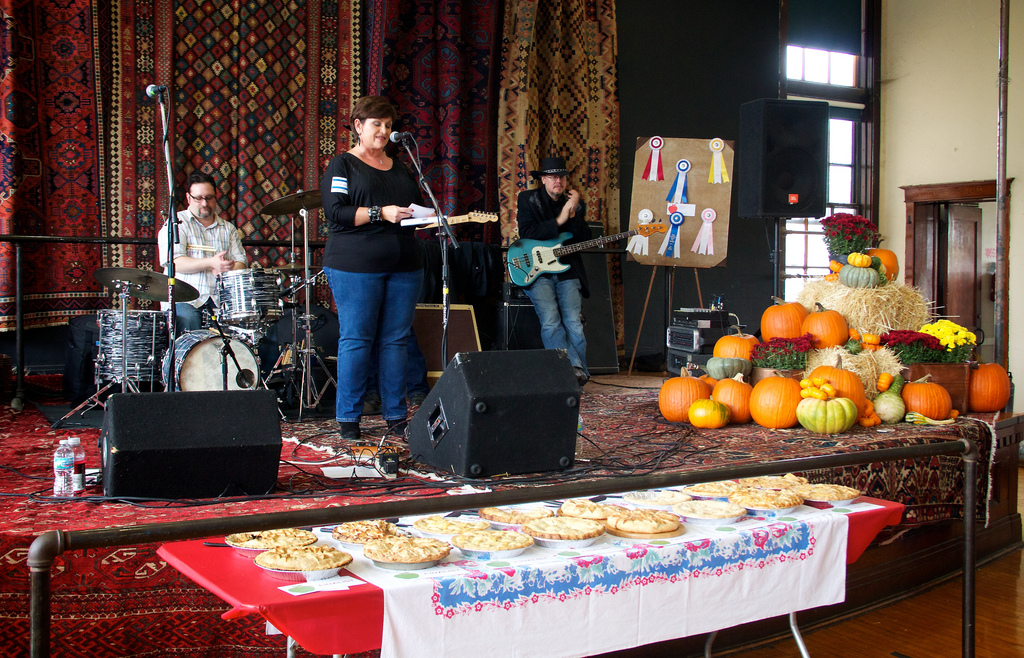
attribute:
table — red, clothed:
[146, 470, 921, 648]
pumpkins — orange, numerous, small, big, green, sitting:
[636, 214, 1008, 442]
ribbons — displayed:
[648, 135, 725, 257]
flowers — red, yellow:
[803, 207, 881, 287]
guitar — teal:
[488, 222, 590, 287]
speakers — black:
[729, 93, 840, 231]